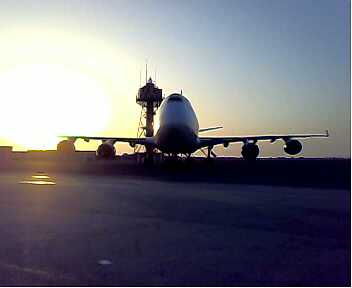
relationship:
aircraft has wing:
[56, 93, 328, 163] [198, 130, 331, 161]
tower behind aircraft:
[134, 63, 164, 168] [56, 93, 328, 163]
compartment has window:
[155, 92, 195, 127] [167, 96, 182, 103]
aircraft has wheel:
[56, 93, 328, 163] [140, 153, 152, 171]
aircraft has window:
[56, 93, 328, 163] [167, 96, 182, 103]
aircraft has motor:
[56, 93, 328, 163] [238, 141, 264, 162]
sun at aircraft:
[21, 132, 59, 152] [56, 93, 328, 163]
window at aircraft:
[167, 96, 182, 103] [56, 93, 328, 163]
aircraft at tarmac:
[56, 93, 328, 163] [2, 155, 351, 286]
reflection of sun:
[11, 179, 51, 184] [21, 132, 59, 152]